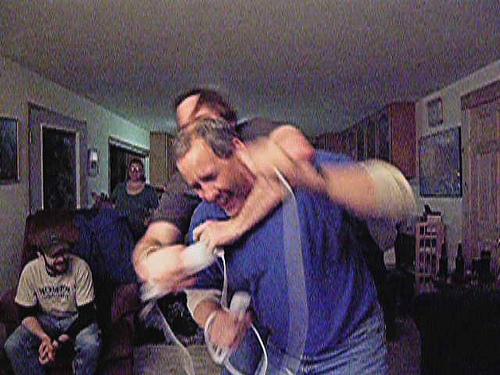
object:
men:
[127, 73, 423, 373]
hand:
[192, 218, 234, 257]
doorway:
[40, 125, 80, 212]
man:
[1, 208, 101, 375]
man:
[132, 84, 420, 375]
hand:
[204, 310, 253, 349]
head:
[125, 157, 146, 185]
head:
[24, 208, 81, 273]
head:
[174, 87, 237, 128]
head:
[169, 119, 253, 218]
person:
[171, 88, 223, 130]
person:
[128, 160, 145, 183]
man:
[183, 117, 400, 375]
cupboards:
[305, 100, 417, 180]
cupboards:
[149, 130, 177, 189]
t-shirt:
[14, 253, 96, 319]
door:
[458, 80, 499, 265]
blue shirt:
[187, 148, 376, 360]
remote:
[210, 290, 253, 365]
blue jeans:
[4, 315, 103, 374]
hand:
[38, 340, 58, 366]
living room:
[0, 0, 500, 375]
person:
[174, 121, 258, 217]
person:
[37, 238, 70, 274]